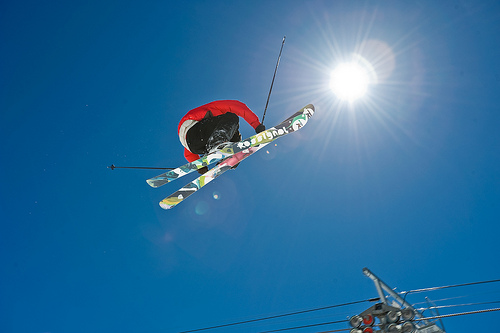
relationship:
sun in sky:
[267, 1, 444, 166] [2, 3, 497, 331]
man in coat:
[177, 99, 265, 175] [177, 99, 262, 162]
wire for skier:
[182, 276, 498, 331] [106, 35, 317, 214]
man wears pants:
[177, 99, 265, 175] [185, 110, 241, 153]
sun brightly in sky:
[267, 1, 444, 166] [32, 11, 470, 319]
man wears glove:
[177, 99, 265, 175] [256, 119, 271, 133]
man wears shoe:
[177, 99, 265, 175] [207, 127, 230, 147]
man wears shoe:
[177, 99, 265, 175] [227, 157, 243, 170]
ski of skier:
[146, 115, 308, 185] [163, 94, 264, 160]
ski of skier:
[159, 159, 244, 209] [163, 94, 264, 160]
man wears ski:
[177, 99, 265, 175] [158, 103, 315, 210]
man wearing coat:
[162, 86, 265, 139] [164, 93, 265, 147]